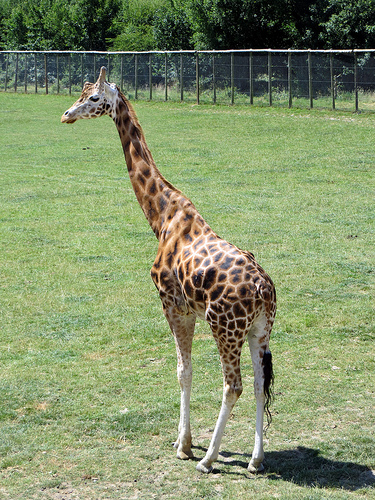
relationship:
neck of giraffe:
[121, 123, 181, 214] [58, 66, 278, 475]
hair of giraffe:
[260, 352, 274, 438] [58, 66, 278, 475]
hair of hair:
[262, 362, 274, 423] [260, 352, 274, 438]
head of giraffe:
[53, 78, 125, 120] [58, 66, 278, 475]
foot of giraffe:
[174, 434, 193, 461] [58, 66, 278, 475]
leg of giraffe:
[194, 332, 241, 469] [58, 66, 278, 475]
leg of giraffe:
[247, 348, 277, 472] [58, 66, 278, 475]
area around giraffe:
[9, 80, 365, 489] [58, 66, 278, 475]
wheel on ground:
[8, 80, 32, 90] [1, 69, 372, 482]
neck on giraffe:
[121, 123, 181, 214] [58, 66, 278, 475]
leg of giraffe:
[206, 332, 240, 456] [58, 66, 278, 475]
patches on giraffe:
[190, 268, 237, 299] [58, 66, 278, 475]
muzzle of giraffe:
[55, 98, 99, 123] [58, 66, 278, 475]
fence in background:
[9, 51, 374, 85] [17, 11, 374, 116]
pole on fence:
[262, 52, 276, 103] [9, 51, 374, 85]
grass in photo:
[2, 94, 360, 499] [3, 7, 365, 496]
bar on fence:
[7, 50, 374, 56] [9, 51, 374, 85]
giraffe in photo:
[58, 66, 278, 475] [3, 7, 365, 496]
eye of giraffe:
[82, 89, 107, 107] [58, 66, 278, 475]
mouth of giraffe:
[62, 115, 78, 128] [58, 66, 278, 475]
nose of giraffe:
[53, 112, 67, 120] [58, 66, 278, 475]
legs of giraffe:
[157, 308, 203, 453] [58, 66, 278, 475]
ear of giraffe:
[99, 91, 117, 108] [58, 66, 278, 475]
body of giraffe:
[128, 218, 274, 343] [58, 66, 278, 475]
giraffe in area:
[58, 66, 278, 475] [0, 61, 370, 499]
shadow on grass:
[264, 430, 357, 499] [2, 94, 360, 499]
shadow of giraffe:
[264, 430, 357, 499] [58, 66, 278, 475]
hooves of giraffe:
[169, 443, 282, 487] [58, 66, 278, 475]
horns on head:
[92, 62, 117, 76] [53, 78, 125, 120]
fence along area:
[9, 51, 374, 85] [0, 61, 370, 499]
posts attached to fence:
[200, 64, 310, 84] [9, 51, 374, 85]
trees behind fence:
[9, 7, 341, 79] [9, 51, 374, 85]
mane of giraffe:
[138, 117, 167, 171] [58, 66, 278, 475]